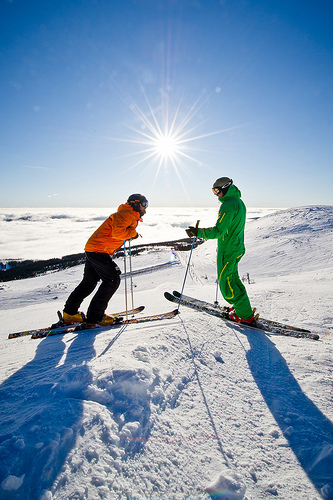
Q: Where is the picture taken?
A: Ski slope.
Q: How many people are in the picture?
A: Two.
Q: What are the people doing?
A: Skiing.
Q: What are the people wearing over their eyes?
A: Goggles.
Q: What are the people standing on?
A: Skis.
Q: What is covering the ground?
A: Snow.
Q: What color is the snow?
A: White.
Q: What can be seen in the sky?
A: Sun.